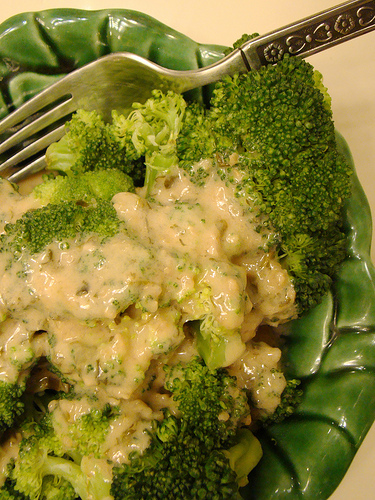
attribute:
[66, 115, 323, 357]
broccoli — upclose, flavored, delicious looking, small, green, steamed, mushy, raw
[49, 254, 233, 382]
cheese sauce — creamy, yellow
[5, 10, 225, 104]
bowl — green, ceramic, shiny, leaf pattern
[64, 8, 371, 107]
fork — silver, metal, decorated, shiny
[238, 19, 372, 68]
handle — metal, decorative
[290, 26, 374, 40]
design — hearts, heart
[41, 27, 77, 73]
cracks — paint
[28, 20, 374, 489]
plate — ceramic, green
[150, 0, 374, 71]
background — tan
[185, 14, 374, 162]
tabletop — white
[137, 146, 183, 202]
stem — eatable